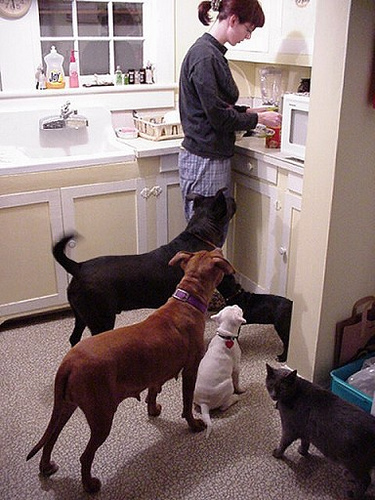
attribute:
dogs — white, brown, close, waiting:
[96, 215, 306, 415]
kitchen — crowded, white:
[10, 15, 338, 226]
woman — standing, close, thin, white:
[171, 4, 268, 168]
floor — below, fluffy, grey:
[144, 414, 271, 495]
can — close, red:
[262, 125, 288, 159]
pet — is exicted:
[188, 298, 255, 435]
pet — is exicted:
[47, 182, 241, 259]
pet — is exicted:
[221, 274, 288, 310]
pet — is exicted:
[25, 249, 215, 489]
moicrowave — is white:
[279, 92, 305, 161]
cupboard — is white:
[271, 2, 314, 60]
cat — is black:
[262, 363, 373, 498]